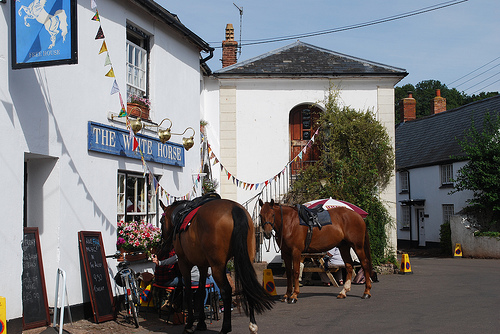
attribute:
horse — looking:
[257, 194, 377, 307]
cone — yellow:
[397, 249, 413, 278]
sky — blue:
[156, 1, 498, 96]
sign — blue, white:
[9, 0, 79, 70]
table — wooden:
[276, 244, 353, 294]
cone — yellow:
[388, 251, 412, 280]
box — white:
[119, 241, 163, 263]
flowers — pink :
[114, 218, 163, 248]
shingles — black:
[212, 38, 419, 88]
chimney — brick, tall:
[216, 15, 242, 77]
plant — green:
[288, 86, 399, 279]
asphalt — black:
[78, 233, 497, 332]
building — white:
[2, 1, 422, 323]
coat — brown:
[171, 187, 219, 272]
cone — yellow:
[449, 238, 465, 261]